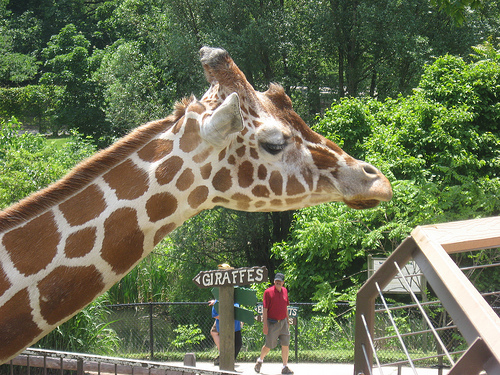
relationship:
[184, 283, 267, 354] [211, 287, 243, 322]
man with shirt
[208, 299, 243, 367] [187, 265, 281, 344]
man behind sign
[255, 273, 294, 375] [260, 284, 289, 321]
man wearing shirt